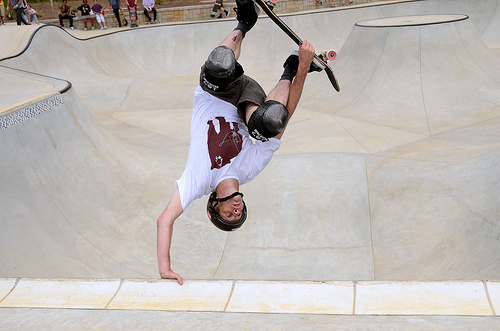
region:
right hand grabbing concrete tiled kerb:
[153, 265, 184, 288]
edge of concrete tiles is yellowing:
[1, 297, 497, 314]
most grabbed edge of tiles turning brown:
[1, 272, 499, 285]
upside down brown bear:
[203, 114, 244, 174]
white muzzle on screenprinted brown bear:
[213, 152, 225, 167]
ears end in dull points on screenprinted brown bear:
[206, 157, 233, 172]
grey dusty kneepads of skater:
[200, 41, 290, 131]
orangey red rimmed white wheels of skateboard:
[265, 0, 341, 61]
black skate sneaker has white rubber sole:
[284, 47, 330, 71]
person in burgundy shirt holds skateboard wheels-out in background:
[126, 0, 142, 30]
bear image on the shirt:
[208, 109, 247, 171]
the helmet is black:
[206, 212, 261, 240]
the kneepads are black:
[253, 102, 295, 146]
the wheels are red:
[327, 50, 342, 63]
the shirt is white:
[190, 120, 269, 182]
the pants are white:
[93, 12, 106, 22]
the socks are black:
[282, 66, 292, 81]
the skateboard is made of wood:
[271, 13, 363, 87]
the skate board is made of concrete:
[363, 175, 425, 236]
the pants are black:
[56, 13, 78, 26]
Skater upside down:
[141, 4, 349, 298]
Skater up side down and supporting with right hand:
[151, 0, 356, 306]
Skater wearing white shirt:
[143, 1, 349, 303]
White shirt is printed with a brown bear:
[174, 84, 284, 202]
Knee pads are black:
[200, 35, 300, 149]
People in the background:
[1, 1, 302, 31]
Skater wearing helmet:
[141, 0, 348, 299]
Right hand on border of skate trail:
[140, 159, 206, 295]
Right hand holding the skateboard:
[271, 26, 338, 126]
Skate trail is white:
[8, 5, 499, 326]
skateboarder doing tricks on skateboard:
[272, 5, 353, 96]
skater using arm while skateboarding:
[155, 200, 193, 280]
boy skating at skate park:
[113, 2, 368, 272]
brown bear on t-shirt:
[191, 91, 259, 179]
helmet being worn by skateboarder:
[203, 195, 255, 226]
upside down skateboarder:
[150, 2, 365, 293]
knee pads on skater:
[200, 45, 237, 87]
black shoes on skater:
[223, 0, 263, 35]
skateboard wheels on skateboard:
[323, 40, 338, 68]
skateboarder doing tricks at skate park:
[159, 16, 366, 287]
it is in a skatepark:
[32, 31, 438, 271]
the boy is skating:
[142, 0, 400, 265]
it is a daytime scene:
[86, 3, 375, 316]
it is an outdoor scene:
[104, 6, 421, 276]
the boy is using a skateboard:
[85, 3, 395, 278]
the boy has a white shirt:
[97, 3, 387, 238]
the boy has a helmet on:
[123, 17, 341, 260]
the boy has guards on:
[87, 11, 429, 244]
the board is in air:
[139, 16, 384, 263]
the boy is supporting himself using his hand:
[26, 11, 391, 273]